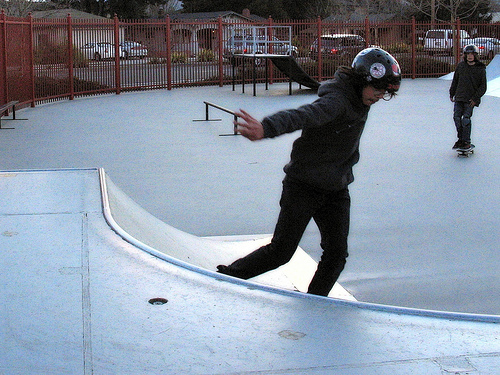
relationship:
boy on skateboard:
[448, 42, 483, 143] [452, 137, 478, 157]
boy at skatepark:
[448, 42, 483, 143] [7, 2, 500, 374]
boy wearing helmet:
[211, 39, 401, 320] [350, 41, 401, 92]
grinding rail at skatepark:
[195, 97, 245, 137] [7, 2, 500, 374]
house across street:
[6, 3, 135, 59] [18, 54, 499, 84]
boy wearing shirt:
[211, 39, 401, 320] [259, 66, 371, 193]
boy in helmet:
[448, 42, 483, 143] [465, 45, 480, 55]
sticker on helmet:
[371, 61, 388, 81] [350, 41, 401, 92]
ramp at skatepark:
[3, 169, 498, 374] [7, 2, 500, 374]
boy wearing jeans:
[211, 39, 401, 320] [230, 167, 356, 297]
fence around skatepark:
[4, 10, 499, 121] [7, 2, 500, 374]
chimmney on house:
[238, 6, 248, 22] [142, 8, 290, 75]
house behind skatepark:
[6, 3, 135, 59] [7, 2, 500, 374]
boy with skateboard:
[448, 42, 483, 143] [452, 137, 478, 157]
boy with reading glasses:
[211, 39, 401, 320] [369, 86, 394, 102]